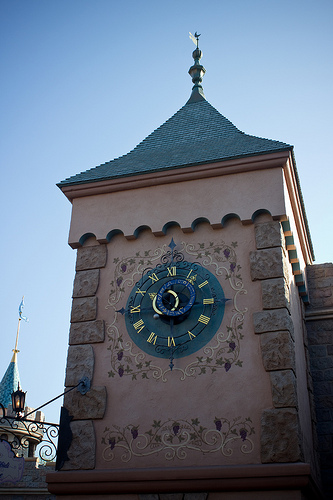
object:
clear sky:
[0, 0, 332, 464]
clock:
[115, 236, 233, 372]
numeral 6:
[167, 336, 176, 348]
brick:
[58, 243, 108, 470]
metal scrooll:
[0, 402, 61, 463]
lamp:
[16, 400, 21, 407]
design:
[101, 416, 256, 462]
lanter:
[10, 381, 27, 418]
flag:
[18, 295, 29, 323]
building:
[0, 295, 46, 486]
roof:
[55, 31, 316, 265]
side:
[285, 249, 315, 463]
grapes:
[224, 340, 236, 372]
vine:
[143, 417, 209, 450]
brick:
[248, 220, 304, 462]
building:
[45, 31, 333, 500]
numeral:
[130, 266, 214, 347]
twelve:
[166, 266, 176, 277]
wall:
[304, 262, 333, 500]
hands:
[168, 235, 233, 306]